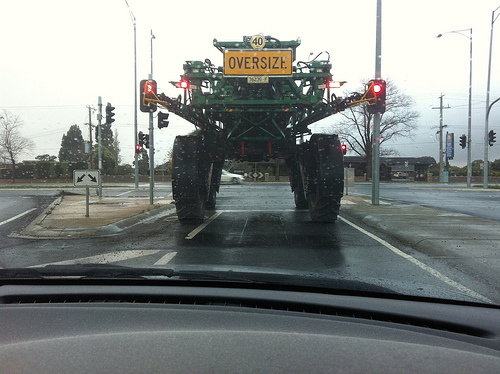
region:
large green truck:
[130, 36, 381, 228]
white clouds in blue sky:
[391, 21, 426, 41]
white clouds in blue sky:
[440, 43, 478, 90]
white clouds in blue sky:
[2, 19, 42, 40]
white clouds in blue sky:
[17, 49, 51, 87]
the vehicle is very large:
[137, 33, 378, 226]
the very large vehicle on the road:
[1, 34, 498, 309]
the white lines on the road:
[0, 180, 498, 305]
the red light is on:
[144, 82, 154, 93]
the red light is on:
[179, 78, 187, 90]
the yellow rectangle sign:
[222, 48, 292, 77]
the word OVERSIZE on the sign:
[222, 49, 292, 76]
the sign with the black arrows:
[72, 169, 101, 186]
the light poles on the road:
[2, 0, 499, 305]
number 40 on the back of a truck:
[247, 35, 267, 50]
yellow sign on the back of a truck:
[223, 48, 295, 77]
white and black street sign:
[69, 163, 99, 189]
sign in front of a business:
[442, 129, 457, 164]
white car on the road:
[186, 161, 247, 186]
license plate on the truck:
[246, 71, 273, 89]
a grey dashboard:
[0, 273, 499, 373]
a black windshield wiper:
[1, 256, 396, 293]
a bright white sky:
[0, 0, 496, 167]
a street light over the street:
[435, 25, 471, 182]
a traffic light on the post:
[455, 132, 470, 147]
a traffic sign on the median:
[71, 167, 96, 183]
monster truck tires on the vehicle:
[170, 132, 206, 224]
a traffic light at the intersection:
[368, 79, 387, 116]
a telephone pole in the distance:
[431, 93, 452, 181]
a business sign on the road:
[443, 131, 456, 172]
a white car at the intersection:
[221, 167, 246, 186]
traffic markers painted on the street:
[138, 219, 207, 271]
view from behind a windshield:
[7, 12, 485, 357]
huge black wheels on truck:
[126, 29, 385, 221]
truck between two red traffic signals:
[138, 0, 388, 224]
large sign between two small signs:
[211, 32, 298, 85]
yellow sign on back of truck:
[224, 48, 293, 74]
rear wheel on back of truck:
[305, 134, 344, 221]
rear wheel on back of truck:
[171, 135, 208, 225]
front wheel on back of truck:
[293, 144, 309, 211]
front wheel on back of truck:
[207, 173, 217, 210]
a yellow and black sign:
[221, 50, 296, 80]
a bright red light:
[371, 80, 386, 102]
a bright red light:
[141, 82, 156, 97]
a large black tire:
[164, 127, 207, 220]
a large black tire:
[196, 146, 219, 222]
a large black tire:
[284, 150, 304, 212]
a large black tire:
[302, 135, 344, 227]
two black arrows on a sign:
[72, 169, 100, 189]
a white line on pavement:
[156, 198, 228, 238]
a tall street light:
[434, 22, 479, 184]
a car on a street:
[200, 158, 242, 186]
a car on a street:
[135, 34, 385, 222]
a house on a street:
[338, 150, 446, 190]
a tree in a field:
[3, 112, 31, 165]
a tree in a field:
[53, 119, 85, 174]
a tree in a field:
[87, 112, 123, 171]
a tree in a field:
[130, 143, 152, 180]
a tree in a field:
[326, 78, 408, 179]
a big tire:
[305, 120, 350, 220]